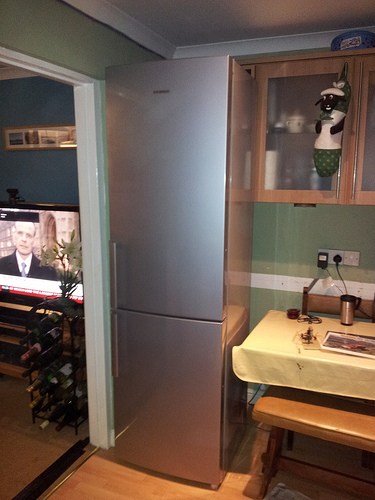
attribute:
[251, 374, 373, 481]
bench — padded, wooden, leather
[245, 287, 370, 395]
tablecloth — yellow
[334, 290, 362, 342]
mug — black, silver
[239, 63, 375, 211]
cupboard — wooden, clear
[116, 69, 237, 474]
fridge — tall, silver, stainless steel, grey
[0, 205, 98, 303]
television — on, flat-screen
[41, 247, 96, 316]
flowers — white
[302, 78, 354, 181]
bag — green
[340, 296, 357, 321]
cup — silver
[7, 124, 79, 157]
photos — framed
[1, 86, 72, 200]
wall — blue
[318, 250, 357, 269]
outlet — white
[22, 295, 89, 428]
wine rack — black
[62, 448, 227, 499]
floor — hardwood, wooden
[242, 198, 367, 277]
wall — green